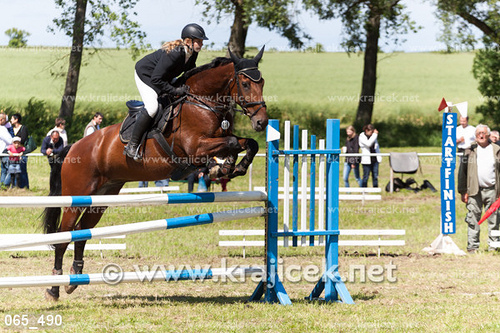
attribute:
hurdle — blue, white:
[1, 118, 358, 304]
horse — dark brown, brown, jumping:
[46, 46, 270, 304]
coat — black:
[345, 135, 361, 166]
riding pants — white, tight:
[132, 69, 158, 116]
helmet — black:
[180, 24, 210, 39]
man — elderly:
[456, 122, 500, 253]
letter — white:
[446, 113, 454, 125]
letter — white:
[443, 145, 452, 158]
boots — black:
[126, 108, 154, 161]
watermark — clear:
[104, 256, 400, 291]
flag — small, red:
[436, 97, 452, 113]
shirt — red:
[6, 146, 27, 163]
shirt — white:
[475, 145, 496, 187]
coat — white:
[359, 133, 382, 164]